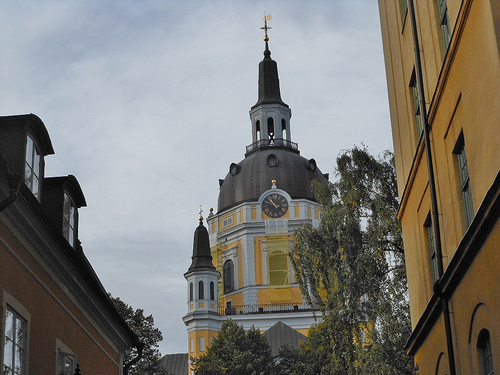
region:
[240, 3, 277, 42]
part of a cross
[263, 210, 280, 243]
part of a window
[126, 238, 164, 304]
part of a cloud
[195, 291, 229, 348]
part of a window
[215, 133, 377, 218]
a gray dome shape roof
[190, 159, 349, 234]
a gray dome shape roof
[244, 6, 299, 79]
a cross at the tip of the tower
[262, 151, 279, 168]
a circular window in building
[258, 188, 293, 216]
a black clock on a building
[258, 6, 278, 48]
a cross on top of a bell tower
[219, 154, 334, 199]
a black domes roof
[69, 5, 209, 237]
thick white clouds covering the sky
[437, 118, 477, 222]
a window in building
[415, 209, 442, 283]
a window in building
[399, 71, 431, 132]
a window in building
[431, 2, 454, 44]
a window in building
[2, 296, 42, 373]
a window in building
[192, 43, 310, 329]
this is a church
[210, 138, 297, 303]
the wall is yellow in color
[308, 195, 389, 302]
these are the leaves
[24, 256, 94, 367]
this is a building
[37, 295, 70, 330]
the wall is brown in color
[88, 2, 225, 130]
this is the sky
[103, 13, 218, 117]
the sky is grey in color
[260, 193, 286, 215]
this is the clock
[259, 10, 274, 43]
this is the antennae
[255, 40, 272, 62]
the top is sharp